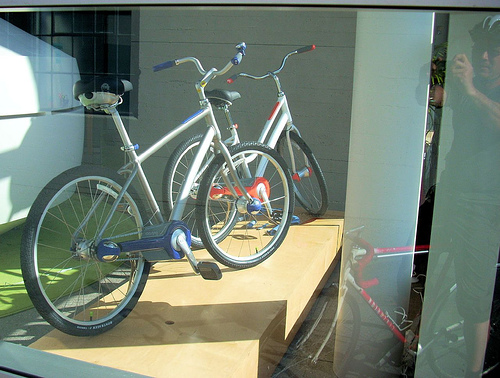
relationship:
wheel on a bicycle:
[4, 153, 159, 374] [17, 37, 290, 339]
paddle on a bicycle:
[200, 263, 221, 282] [17, 37, 290, 339]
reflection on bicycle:
[263, 7, 498, 377] [285, 217, 496, 376]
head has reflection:
[453, 30, 498, 107] [463, 13, 498, 40]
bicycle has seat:
[17, 37, 290, 339] [73, 74, 135, 115]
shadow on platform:
[66, 287, 296, 352] [33, 206, 365, 376]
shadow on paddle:
[226, 228, 258, 245] [200, 263, 221, 282]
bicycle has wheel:
[17, 37, 290, 339] [4, 153, 159, 374]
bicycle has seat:
[17, 37, 290, 339] [57, 75, 134, 109]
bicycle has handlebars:
[17, 37, 290, 339] [162, 39, 336, 107]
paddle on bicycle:
[189, 252, 226, 288] [17, 37, 290, 339]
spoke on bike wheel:
[50, 209, 133, 304] [18, 164, 150, 338]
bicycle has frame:
[158, 45, 338, 226] [209, 43, 311, 180]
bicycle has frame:
[17, 37, 290, 339] [104, 43, 273, 277]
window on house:
[26, 9, 146, 122] [4, 6, 350, 213]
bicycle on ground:
[17, 37, 290, 339] [0, 199, 353, 373]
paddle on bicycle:
[200, 263, 221, 282] [17, 37, 290, 339]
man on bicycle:
[362, 16, 498, 377] [17, 37, 290, 339]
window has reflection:
[7, 9, 493, 375] [305, 27, 493, 367]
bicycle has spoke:
[17, 37, 290, 339] [56, 190, 101, 240]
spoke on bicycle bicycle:
[50, 273, 86, 303] [163, 45, 334, 250]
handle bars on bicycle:
[151, 40, 246, 75] [17, 37, 290, 339]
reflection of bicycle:
[337, 229, 469, 377] [333, 219, 417, 355]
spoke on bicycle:
[256, 164, 279, 202] [17, 37, 290, 339]